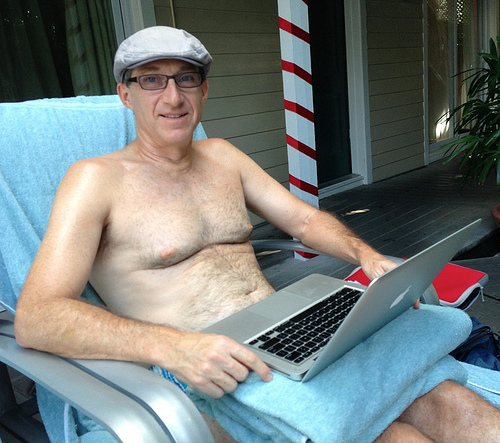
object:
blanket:
[191, 303, 472, 443]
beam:
[266, 0, 321, 261]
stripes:
[276, 7, 313, 197]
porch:
[377, 140, 482, 225]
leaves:
[465, 100, 483, 149]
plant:
[440, 36, 484, 202]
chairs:
[0, 90, 500, 443]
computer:
[189, 214, 482, 385]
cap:
[113, 24, 217, 88]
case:
[342, 236, 480, 313]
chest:
[117, 179, 271, 319]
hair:
[137, 171, 240, 296]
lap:
[192, 301, 469, 443]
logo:
[388, 283, 413, 310]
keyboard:
[247, 287, 364, 363]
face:
[131, 59, 205, 144]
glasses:
[120, 69, 207, 90]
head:
[110, 24, 212, 148]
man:
[13, 24, 500, 443]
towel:
[0, 92, 500, 441]